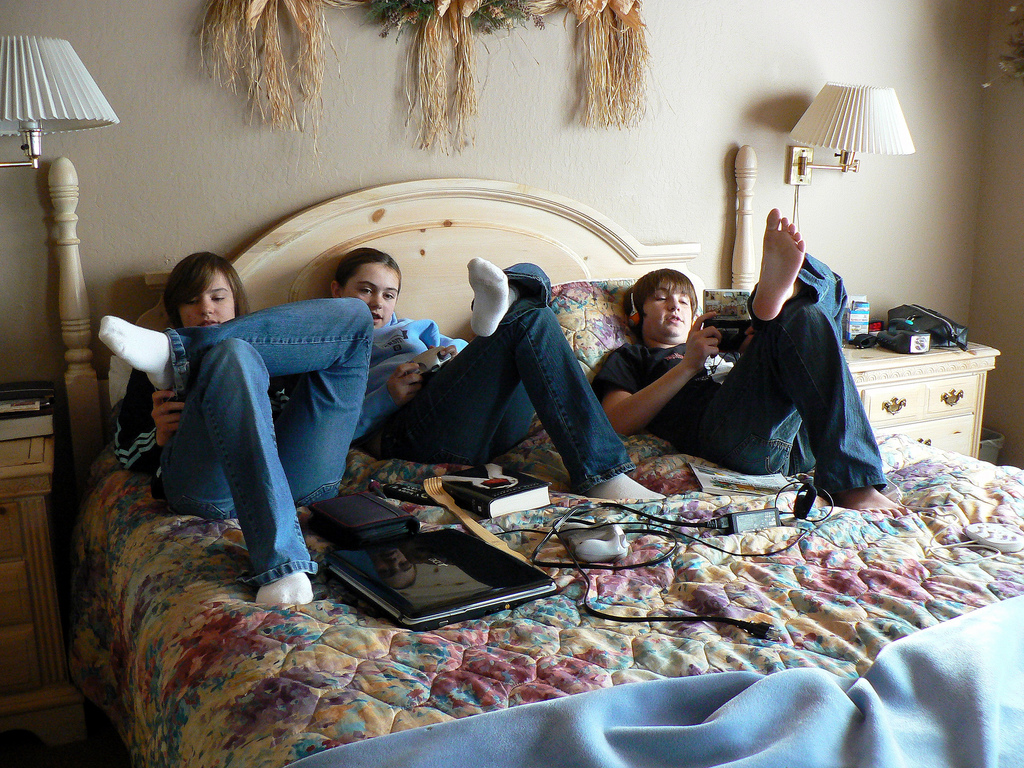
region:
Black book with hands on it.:
[427, 459, 563, 513]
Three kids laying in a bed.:
[99, 208, 913, 610]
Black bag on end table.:
[886, 303, 967, 346]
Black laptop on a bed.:
[320, 524, 551, 624]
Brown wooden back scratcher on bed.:
[422, 476, 558, 588]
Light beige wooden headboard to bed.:
[35, 141, 770, 458]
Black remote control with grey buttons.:
[384, 481, 452, 510]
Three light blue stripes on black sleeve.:
[109, 411, 163, 475]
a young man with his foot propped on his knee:
[589, 210, 906, 524]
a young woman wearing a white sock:
[321, 244, 664, 511]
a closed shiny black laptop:
[318, 529, 556, 625]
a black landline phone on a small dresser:
[835, 305, 1000, 461]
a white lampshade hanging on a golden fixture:
[785, 83, 913, 189]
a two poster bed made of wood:
[36, 144, 1021, 767]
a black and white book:
[438, 459, 552, 518]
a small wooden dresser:
[842, 327, 999, 460]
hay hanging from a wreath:
[190, 0, 652, 156]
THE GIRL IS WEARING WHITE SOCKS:
[459, 251, 656, 517]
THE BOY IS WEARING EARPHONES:
[598, 269, 653, 328]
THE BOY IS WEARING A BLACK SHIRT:
[588, 321, 750, 467]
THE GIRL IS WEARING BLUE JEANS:
[130, 282, 383, 592]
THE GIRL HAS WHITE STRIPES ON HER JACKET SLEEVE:
[96, 394, 169, 477]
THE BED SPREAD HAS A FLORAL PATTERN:
[32, 380, 1020, 767]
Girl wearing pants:
[147, 280, 389, 600]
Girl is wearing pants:
[147, 283, 383, 603]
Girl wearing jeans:
[147, 280, 381, 582]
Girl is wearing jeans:
[125, 282, 381, 606]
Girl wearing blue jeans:
[152, 285, 380, 577]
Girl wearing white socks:
[93, 304, 324, 617]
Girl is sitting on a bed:
[78, 201, 388, 636]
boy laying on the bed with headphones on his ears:
[604, 233, 902, 522]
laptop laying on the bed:
[329, 527, 549, 632]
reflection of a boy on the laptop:
[359, 535, 435, 590]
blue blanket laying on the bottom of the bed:
[272, 590, 1022, 762]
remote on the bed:
[371, 473, 435, 505]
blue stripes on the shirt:
[105, 435, 147, 483]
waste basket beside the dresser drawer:
[977, 424, 1010, 466]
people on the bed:
[69, 124, 933, 714]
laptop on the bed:
[303, 464, 705, 709]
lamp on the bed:
[0, 40, 140, 136]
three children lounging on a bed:
[128, 224, 866, 572]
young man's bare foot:
[753, 209, 811, 336]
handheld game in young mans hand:
[698, 279, 756, 360]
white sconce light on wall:
[776, 69, 909, 200]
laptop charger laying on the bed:
[555, 490, 802, 647]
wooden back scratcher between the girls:
[415, 472, 472, 526]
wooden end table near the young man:
[870, 335, 995, 443]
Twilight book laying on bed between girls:
[444, 461, 553, 519]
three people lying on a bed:
[86, 204, 887, 619]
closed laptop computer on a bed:
[318, 523, 587, 647]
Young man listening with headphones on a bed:
[589, 201, 907, 525]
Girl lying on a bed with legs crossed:
[301, 220, 665, 519]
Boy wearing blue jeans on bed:
[92, 210, 384, 625]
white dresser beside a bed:
[814, 305, 1007, 480]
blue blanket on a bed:
[294, 590, 1022, 767]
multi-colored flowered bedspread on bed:
[73, 431, 1022, 765]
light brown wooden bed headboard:
[156, 167, 701, 345]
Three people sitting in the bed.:
[151, 215, 828, 552]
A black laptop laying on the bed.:
[326, 525, 539, 644]